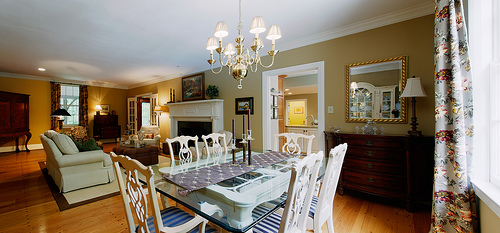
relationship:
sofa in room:
[33, 118, 127, 216] [3, 2, 499, 232]